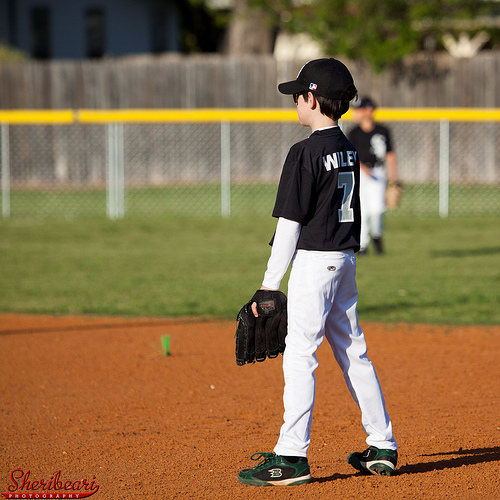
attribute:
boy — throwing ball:
[233, 56, 397, 486]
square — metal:
[2, 117, 77, 163]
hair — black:
[324, 101, 341, 121]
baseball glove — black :
[230, 286, 293, 366]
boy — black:
[183, 42, 405, 409]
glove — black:
[211, 290, 300, 370]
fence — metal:
[2, 123, 498, 220]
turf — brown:
[0, 312, 499, 496]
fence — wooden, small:
[1, 112, 498, 222]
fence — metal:
[20, 110, 185, 203]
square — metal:
[451, 122, 498, 217]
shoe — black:
[345, 442, 395, 474]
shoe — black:
[237, 453, 312, 487]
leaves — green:
[215, 0, 498, 74]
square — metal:
[185, 130, 195, 140]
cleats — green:
[203, 454, 440, 487]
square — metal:
[54, 146, 68, 159]